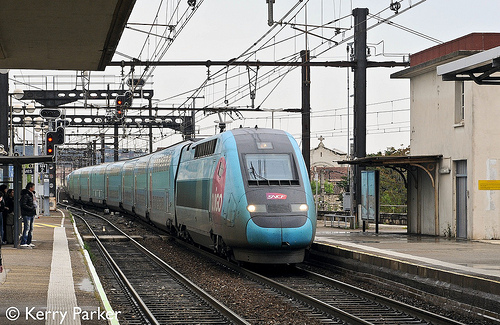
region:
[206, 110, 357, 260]
front of the train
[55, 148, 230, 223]
side of the train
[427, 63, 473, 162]
window on the building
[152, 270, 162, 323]
this is a railway track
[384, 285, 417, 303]
this is a railway track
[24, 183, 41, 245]
this is a person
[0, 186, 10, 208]
this is a person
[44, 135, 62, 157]
these are traffic lights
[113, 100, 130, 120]
these are traffic lights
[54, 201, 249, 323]
a long empty train track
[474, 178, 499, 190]
a yellow sign on the wall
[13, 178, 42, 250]
a man in a black coat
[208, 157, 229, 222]
a red logo on a train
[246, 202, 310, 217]
two train head lights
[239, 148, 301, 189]
front window of a train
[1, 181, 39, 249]
a group of people waiting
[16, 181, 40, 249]
man at a train stop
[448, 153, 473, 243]
a blue door on a white building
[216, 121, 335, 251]
front of the train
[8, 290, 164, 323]
name in bottom left corner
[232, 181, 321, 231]
lights on front of train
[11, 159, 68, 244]
person next to tracks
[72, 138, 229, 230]
side of the train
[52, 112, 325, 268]
blue train on tracks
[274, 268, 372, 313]
track under the train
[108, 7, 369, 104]
things above the train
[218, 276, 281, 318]
rocks in between tracks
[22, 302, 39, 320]
white print style letter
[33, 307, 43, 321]
white print style letter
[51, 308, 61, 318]
white print style letter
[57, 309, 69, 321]
white print style letter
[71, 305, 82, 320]
white print style letter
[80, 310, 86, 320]
white print style letter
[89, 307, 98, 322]
white print style letter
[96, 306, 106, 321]
white print style letter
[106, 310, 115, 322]
white print style letter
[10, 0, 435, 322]
metal frames above train tracks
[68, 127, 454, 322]
blue commuter train on tracks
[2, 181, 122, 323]
people on train platform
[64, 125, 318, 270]
train is on the track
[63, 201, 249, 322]
track is at the train depot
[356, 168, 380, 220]
sign is attached to pole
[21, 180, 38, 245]
person is standing by track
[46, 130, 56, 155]
light is red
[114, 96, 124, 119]
light is red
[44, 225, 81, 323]
white line is beside train track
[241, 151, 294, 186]
window of a train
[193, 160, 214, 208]
window of a train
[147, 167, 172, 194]
window of a train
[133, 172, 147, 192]
window of a train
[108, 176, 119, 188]
window of a train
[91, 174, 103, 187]
window of a train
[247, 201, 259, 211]
the light is on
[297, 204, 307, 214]
the light is on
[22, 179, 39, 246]
a man is standing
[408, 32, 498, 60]
the roof is brown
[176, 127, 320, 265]
A blue train car.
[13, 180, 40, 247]
A man standing on a platform.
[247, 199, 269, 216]
A headlight on a train car.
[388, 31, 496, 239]
A tall multiple story building.